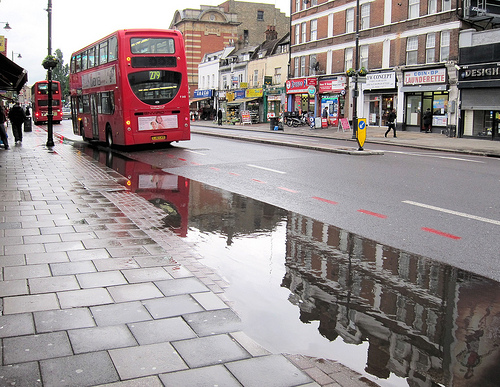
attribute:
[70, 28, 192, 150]
bus — double decker, red, large, biggest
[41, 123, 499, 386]
water puddle — long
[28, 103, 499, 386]
road — damp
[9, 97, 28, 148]
person — walking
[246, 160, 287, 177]
line — broken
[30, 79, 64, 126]
bus — double decker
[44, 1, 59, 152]
lamp post — tall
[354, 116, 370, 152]
flag — yellow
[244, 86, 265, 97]
sign — bright yellow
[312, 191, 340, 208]
line — painted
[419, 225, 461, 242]
dash — red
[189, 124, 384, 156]
walkway — rectangular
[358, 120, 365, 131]
circle — blue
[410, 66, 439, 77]
words coin op — blue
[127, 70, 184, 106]
window — curved